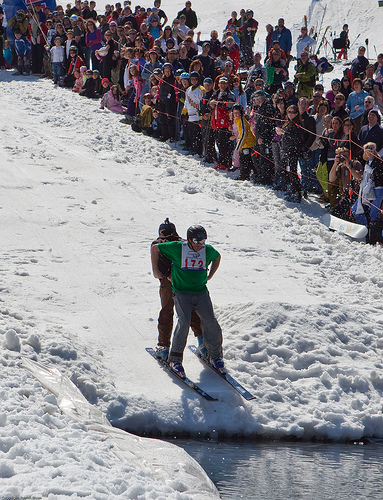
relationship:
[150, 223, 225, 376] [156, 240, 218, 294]
man in shirt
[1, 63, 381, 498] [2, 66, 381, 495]
ground has snow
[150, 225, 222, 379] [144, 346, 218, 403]
man are skis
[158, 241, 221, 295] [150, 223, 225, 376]
shirt a man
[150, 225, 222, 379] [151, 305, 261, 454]
man man light skinned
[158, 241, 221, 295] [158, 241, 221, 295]
shirt a shirt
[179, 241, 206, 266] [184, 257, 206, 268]
bib reads 172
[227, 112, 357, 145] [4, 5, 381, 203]
rope dividing crowd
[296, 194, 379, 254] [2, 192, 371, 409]
snowboard lying on ground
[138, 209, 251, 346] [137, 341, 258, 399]
people on a pair of skis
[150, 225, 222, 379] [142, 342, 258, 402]
man on a pair of skis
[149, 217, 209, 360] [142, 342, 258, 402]
people on a pair of skis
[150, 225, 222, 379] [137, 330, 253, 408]
man on a pair of skis